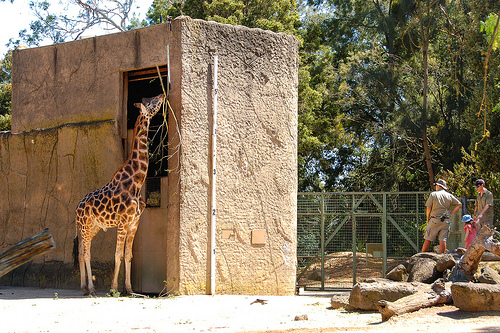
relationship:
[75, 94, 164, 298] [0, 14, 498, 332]
giraffe in a habitat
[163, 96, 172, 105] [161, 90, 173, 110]
food in a dispenser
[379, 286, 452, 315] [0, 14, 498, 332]
log in a habitat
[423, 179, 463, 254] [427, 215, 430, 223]
man has a hand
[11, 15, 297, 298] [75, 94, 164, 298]
buiding next to a giraffe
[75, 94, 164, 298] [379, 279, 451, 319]
giraffe next to wood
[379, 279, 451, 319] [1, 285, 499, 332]
wood on ground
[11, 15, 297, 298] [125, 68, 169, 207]
buiding has a window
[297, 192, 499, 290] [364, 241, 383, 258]
fence has a sign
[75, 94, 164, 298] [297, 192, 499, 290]
giraffe near a fence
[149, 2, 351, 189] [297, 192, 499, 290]
tree near a fence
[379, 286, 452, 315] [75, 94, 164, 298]
log behind a giraffe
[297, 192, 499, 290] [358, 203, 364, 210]
fence has a hole